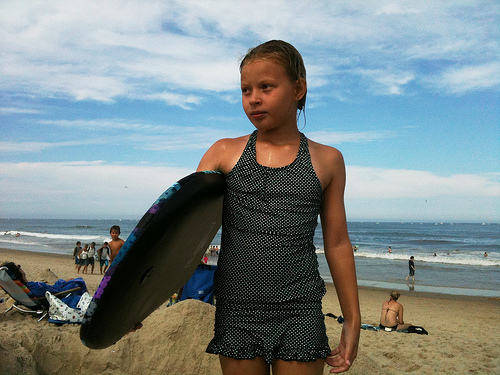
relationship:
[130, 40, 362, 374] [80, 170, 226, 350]
girl holding boogie board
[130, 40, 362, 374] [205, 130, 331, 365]
girl in bathing suit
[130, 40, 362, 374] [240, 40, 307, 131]
girl has wet hair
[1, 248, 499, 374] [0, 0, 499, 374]
sand on beach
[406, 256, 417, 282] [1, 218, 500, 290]
person standing in water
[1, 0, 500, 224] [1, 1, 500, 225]
clouds in sky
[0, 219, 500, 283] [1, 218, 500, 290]
people in water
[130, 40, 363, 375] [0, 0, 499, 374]
girl at beach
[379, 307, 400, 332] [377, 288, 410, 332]
bathing suit on people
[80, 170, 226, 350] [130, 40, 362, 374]
boogie board held by girl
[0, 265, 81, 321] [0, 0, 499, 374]
chair at beach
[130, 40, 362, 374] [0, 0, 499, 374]
girl on beach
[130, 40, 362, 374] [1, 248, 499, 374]
girl on sand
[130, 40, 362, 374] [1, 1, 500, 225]
girl under sky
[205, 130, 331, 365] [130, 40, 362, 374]
bathing suit on girl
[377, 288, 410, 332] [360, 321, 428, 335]
people sitting on towel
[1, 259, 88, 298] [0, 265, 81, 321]
woman on chair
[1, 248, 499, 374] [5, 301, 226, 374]
sand with a hole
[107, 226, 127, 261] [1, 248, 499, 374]
boy on sand